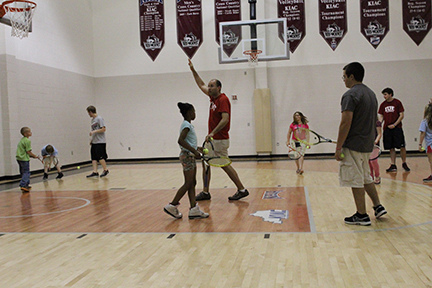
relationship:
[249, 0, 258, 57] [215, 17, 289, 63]
pole securing basketball goal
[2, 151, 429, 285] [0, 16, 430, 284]
floor on basketball court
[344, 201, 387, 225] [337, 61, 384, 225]
tennis shoes on man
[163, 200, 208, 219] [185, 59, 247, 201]
tennis shoes on man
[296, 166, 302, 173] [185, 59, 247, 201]
tennis shoes on man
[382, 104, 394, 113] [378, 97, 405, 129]
writing on shirt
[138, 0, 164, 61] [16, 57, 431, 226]
banner above people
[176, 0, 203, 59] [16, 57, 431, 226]
banner above people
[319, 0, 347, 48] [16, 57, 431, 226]
banner above people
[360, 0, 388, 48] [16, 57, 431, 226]
banner above people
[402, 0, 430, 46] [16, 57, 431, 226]
banner above people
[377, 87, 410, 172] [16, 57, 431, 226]
person among people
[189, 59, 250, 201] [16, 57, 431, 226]
man among people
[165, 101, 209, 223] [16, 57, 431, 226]
person among people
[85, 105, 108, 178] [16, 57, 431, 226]
person among people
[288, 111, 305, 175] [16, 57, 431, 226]
person among people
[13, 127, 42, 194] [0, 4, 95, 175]
boy by wall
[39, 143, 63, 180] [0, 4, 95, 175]
kid by wall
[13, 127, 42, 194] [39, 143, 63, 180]
boy next to kid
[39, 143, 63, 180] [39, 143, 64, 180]
kid next to kid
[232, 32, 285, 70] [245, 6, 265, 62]
basketball hoop hung on pole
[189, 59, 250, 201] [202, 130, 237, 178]
man wearing shorts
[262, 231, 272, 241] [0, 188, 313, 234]
line by square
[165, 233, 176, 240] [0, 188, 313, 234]
line by square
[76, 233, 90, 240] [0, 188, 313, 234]
line by square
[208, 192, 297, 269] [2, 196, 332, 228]
sports logos in red wood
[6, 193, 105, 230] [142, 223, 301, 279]
lines painted on basketball court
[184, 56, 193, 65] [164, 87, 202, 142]
hand holding hand up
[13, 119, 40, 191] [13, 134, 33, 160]
boy in green shirt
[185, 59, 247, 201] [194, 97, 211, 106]
man with his hand raised